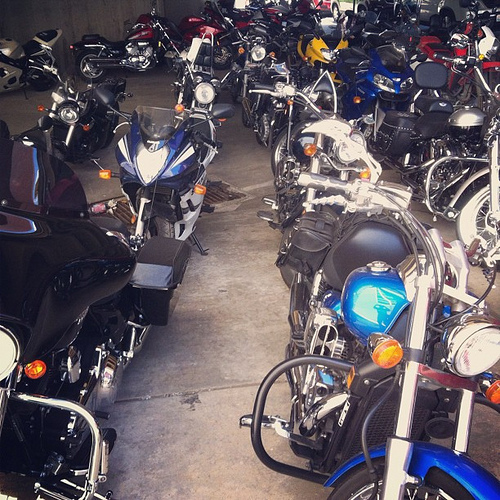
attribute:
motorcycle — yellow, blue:
[137, 150, 166, 176]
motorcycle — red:
[214, 36, 282, 97]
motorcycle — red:
[74, 21, 179, 70]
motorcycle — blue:
[328, 258, 418, 346]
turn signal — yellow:
[93, 167, 116, 185]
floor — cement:
[233, 130, 251, 153]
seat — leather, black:
[81, 30, 101, 42]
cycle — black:
[120, 104, 217, 227]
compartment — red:
[132, 21, 157, 40]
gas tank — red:
[157, 208, 173, 235]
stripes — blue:
[370, 58, 389, 76]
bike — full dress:
[9, 25, 69, 91]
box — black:
[275, 233, 327, 265]